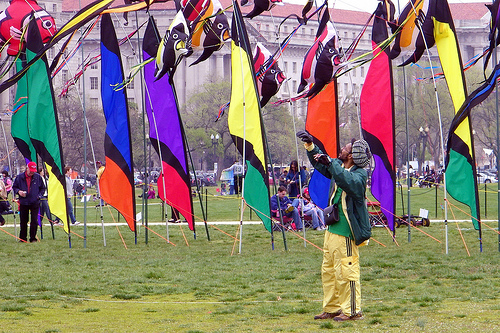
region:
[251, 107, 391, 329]
A man is visible.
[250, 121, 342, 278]
A man is visible.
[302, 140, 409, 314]
A man is visible.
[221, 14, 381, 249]
A man is visible.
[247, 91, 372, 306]
A man is visible.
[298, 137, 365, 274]
A man is visible.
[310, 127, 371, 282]
A man is visible.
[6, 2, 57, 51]
Fish kite in the air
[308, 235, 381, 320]
Yellow wind pants on man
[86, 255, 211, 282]
Green grassy field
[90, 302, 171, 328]
Green bare patch of ground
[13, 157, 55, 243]
Man with a red ball cap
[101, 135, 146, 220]
blue red and black flag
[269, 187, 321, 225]
man and woman sitting down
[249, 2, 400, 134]
building in the background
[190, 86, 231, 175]
green trees in the park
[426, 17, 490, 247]
yellow green and black flag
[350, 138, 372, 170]
grey crocheted dreads hat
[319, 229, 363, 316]
yellow flight pants with black stripes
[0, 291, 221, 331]
area of dead yellow grass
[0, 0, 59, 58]
red clownfish wind flyer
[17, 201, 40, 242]
black old man jeans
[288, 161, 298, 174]
woman's head with dark hair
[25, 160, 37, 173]
man with a red baseball cap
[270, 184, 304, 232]
white man in blue coat sitting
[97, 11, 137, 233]
blue, orange, and black flag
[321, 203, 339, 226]
black satchel hanging around a man's neck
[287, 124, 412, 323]
The man has a round striped headdress.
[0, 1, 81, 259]
The flag is green and yellow.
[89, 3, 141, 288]
The flag is blue and red.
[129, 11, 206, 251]
The flag is red, purple, and black.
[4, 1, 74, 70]
The floating fish is red, white, and black.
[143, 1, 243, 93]
2 decorative fish are overhead.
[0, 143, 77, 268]
The spectator is wearing a red cap.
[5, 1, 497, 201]
A large public building is in the background of this event.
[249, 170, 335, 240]
2 people sit on a bench together.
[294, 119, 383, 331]
The man wears yellow pants and a green shirt.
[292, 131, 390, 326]
this is a man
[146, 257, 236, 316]
this is a grass area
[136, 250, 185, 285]
the grass is green in color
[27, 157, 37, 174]
this is a cap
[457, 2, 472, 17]
this is the roof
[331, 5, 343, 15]
the roof is red in color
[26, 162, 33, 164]
the cap is red in color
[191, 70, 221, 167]
this is a tree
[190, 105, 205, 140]
the tree has green leaves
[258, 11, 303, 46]
this is a building